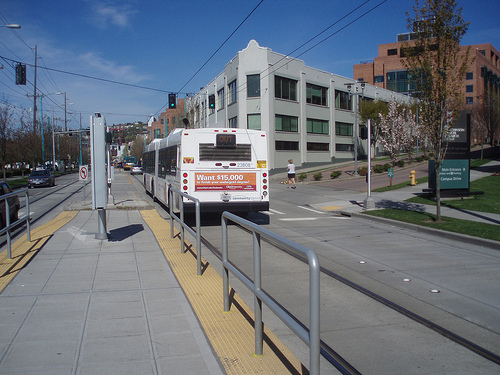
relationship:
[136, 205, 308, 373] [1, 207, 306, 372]
edge of platform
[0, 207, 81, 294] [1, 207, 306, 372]
edge of platform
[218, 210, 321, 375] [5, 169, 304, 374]
railing on ground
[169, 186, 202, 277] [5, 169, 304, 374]
railing on ground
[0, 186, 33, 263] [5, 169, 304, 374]
railing on ground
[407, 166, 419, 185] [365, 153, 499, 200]
fire hydrant on sidewalk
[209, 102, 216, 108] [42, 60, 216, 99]
light hanging from wire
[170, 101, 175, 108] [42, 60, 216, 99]
light hanging from wire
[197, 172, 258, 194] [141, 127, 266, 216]
ad on back of bus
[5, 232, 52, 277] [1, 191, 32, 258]
shadow of railing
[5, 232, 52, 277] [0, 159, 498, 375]
shadow on boulevard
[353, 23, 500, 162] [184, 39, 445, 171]
brick building next to building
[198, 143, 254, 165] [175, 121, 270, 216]
vents on back of bus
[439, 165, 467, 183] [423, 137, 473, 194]
letters on sign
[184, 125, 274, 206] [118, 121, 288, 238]
back of bus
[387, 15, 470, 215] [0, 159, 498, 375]
tree on boulevard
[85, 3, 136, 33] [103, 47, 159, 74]
cloud in sky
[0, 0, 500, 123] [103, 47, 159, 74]
cloud in sky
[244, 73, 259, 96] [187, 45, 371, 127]
window on building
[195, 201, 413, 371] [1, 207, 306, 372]
railing on platform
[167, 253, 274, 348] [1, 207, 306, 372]
paint on platform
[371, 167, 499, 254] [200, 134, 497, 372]
grass on boulevard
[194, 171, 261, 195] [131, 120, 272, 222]
banner on bus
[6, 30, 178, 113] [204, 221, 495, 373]
wires above tracks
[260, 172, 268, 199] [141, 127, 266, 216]
taillights on bus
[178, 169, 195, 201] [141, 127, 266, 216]
taillights on bus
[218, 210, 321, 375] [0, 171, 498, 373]
railing near road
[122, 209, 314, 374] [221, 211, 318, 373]
curb near railing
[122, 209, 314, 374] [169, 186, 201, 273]
curb near railing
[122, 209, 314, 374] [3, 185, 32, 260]
curb near railing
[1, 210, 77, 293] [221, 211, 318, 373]
curb near railing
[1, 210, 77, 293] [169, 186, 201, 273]
curb near railing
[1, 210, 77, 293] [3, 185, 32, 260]
curb near railing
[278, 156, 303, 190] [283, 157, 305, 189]
person wearing shirt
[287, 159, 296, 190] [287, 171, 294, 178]
person wearing shorts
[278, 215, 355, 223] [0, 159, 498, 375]
line marking boulevard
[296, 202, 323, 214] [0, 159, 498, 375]
line marking boulevard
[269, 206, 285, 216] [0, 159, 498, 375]
line marking boulevard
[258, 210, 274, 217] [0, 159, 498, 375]
line marking boulevard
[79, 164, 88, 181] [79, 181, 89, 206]
sign on pole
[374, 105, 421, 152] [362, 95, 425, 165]
flower on tree branches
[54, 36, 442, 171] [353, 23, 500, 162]
building on brick building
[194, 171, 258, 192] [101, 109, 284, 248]
banner on back of bus